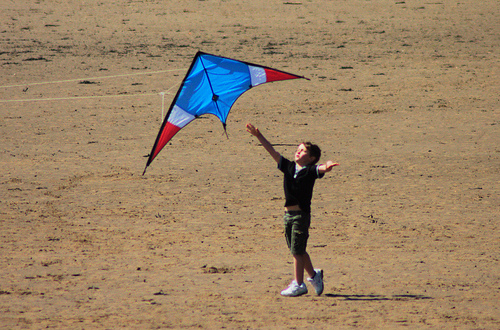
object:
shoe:
[279, 279, 308, 299]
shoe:
[306, 265, 331, 297]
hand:
[242, 120, 264, 137]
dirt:
[4, 3, 499, 328]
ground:
[2, 2, 497, 325]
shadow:
[322, 286, 438, 306]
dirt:
[84, 216, 217, 307]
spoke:
[133, 157, 155, 179]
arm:
[315, 159, 336, 176]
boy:
[242, 124, 342, 299]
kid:
[235, 122, 403, 227]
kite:
[119, 37, 309, 173]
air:
[94, 16, 197, 42]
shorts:
[269, 209, 318, 256]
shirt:
[283, 161, 320, 203]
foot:
[279, 276, 308, 296]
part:
[183, 43, 223, 78]